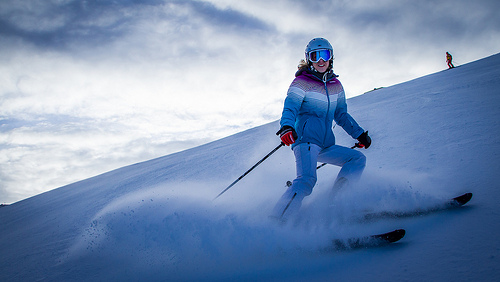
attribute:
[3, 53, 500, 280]
snow — white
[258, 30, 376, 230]
woman — stopped, smiling, sliding, standing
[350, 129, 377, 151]
glove — red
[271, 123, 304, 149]
glove — red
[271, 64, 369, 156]
jacket — white, blue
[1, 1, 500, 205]
clouds — white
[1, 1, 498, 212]
sky — blue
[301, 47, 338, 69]
goggles — white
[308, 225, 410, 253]
ski — black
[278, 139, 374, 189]
pants — blue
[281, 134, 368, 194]
ski pole — black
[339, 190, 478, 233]
ski — black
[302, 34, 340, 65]
helmet — blue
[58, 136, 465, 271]
snow — flying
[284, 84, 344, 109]
stripe — white